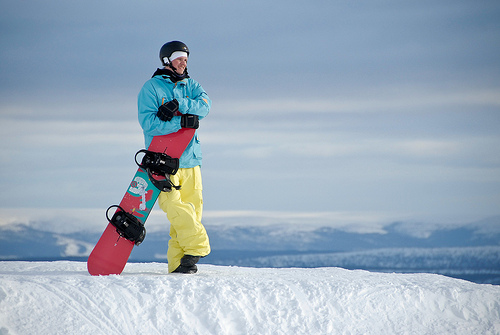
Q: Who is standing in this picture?
A: A woman.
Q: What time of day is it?
A: Daytime.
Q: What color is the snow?
A: White.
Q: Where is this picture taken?
A: A ski slope.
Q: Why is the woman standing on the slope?
A: She is taking a break from snowboarding.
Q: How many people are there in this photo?
A: One.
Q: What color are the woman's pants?
A: Yellow.